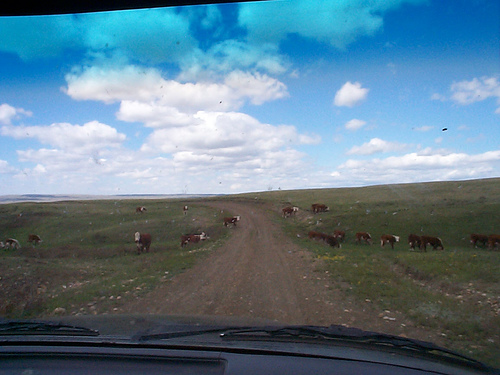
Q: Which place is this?
A: It is a field.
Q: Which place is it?
A: It is a field.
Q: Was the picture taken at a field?
A: Yes, it was taken in a field.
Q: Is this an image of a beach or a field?
A: It is showing a field.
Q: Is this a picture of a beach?
A: No, the picture is showing a field.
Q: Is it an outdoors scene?
A: Yes, it is outdoors.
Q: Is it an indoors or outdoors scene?
A: It is outdoors.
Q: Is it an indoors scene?
A: No, it is outdoors.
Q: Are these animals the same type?
A: Yes, all the animals are cows.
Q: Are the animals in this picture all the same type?
A: Yes, all the animals are cows.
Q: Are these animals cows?
A: Yes, all the animals are cows.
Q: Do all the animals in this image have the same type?
A: Yes, all the animals are cows.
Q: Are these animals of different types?
A: No, all the animals are cows.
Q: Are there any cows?
A: Yes, there are cows.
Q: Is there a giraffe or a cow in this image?
A: Yes, there are cows.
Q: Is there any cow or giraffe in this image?
A: Yes, there are cows.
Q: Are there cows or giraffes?
A: Yes, there are cows.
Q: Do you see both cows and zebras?
A: No, there are cows but no zebras.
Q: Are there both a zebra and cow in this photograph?
A: No, there are cows but no zebras.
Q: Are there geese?
A: No, there are no geese.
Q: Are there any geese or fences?
A: No, there are no geese or fences.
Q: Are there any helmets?
A: No, there are no helmets.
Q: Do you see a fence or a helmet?
A: No, there are no helmets or fences.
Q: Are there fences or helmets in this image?
A: No, there are no helmets or fences.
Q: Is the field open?
A: Yes, the field is open.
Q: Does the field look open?
A: Yes, the field is open.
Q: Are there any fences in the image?
A: No, there are no fences.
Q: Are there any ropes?
A: No, there are no ropes.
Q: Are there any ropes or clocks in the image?
A: No, there are no ropes or clocks.